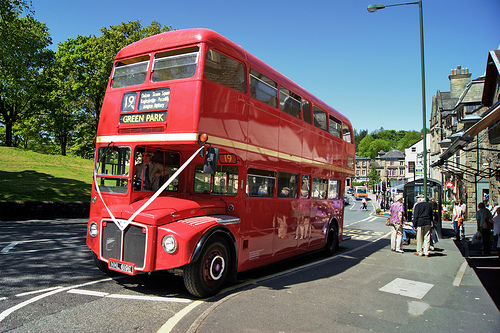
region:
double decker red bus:
[83, 29, 355, 286]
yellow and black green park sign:
[121, 114, 167, 121]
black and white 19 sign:
[122, 93, 135, 109]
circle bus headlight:
[163, 234, 178, 255]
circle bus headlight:
[88, 221, 97, 237]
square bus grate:
[100, 218, 149, 269]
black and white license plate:
[98, 221, 149, 268]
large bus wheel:
[186, 240, 234, 299]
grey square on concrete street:
[376, 273, 433, 299]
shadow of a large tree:
[1, 166, 106, 296]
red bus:
[83, 24, 361, 301]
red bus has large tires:
[84, 22, 354, 298]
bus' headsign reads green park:
[80, 25, 362, 296]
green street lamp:
[363, 2, 430, 249]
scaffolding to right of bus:
[427, 99, 499, 252]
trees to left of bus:
[2, 1, 195, 156]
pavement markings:
[3, 192, 482, 332]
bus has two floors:
[86, 23, 346, 303]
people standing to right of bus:
[381, 190, 499, 262]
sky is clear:
[8, 0, 499, 135]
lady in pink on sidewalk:
[389, 191, 414, 254]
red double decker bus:
[88, 32, 360, 293]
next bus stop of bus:
[108, 92, 176, 130]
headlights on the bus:
[82, 200, 180, 254]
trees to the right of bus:
[7, 1, 104, 160]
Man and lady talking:
[382, 193, 435, 255]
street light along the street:
[346, 0, 449, 172]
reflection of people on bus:
[277, 190, 359, 245]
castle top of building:
[436, 49, 496, 132]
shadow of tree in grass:
[8, 157, 86, 229]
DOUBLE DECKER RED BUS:
[81, 25, 361, 301]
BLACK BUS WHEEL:
[181, 221, 248, 303]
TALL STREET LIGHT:
[365, 0, 448, 203]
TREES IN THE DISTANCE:
[3, 1, 91, 155]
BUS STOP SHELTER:
[401, 171, 454, 241]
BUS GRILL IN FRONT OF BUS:
[95, 212, 157, 278]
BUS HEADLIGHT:
[160, 232, 182, 256]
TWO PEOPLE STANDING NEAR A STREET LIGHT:
[387, 191, 449, 258]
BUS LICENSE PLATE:
[104, 256, 139, 285]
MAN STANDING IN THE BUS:
[128, 141, 188, 196]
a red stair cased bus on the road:
[82, 30, 365, 332]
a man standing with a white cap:
[388, 193, 408, 201]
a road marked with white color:
[44, 280, 193, 327]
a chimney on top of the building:
[448, 59, 478, 77]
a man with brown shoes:
[415, 250, 432, 259]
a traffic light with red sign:
[377, 176, 389, 189]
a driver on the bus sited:
[121, 142, 184, 191]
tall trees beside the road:
[18, 22, 85, 163]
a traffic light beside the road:
[363, 0, 440, 167]